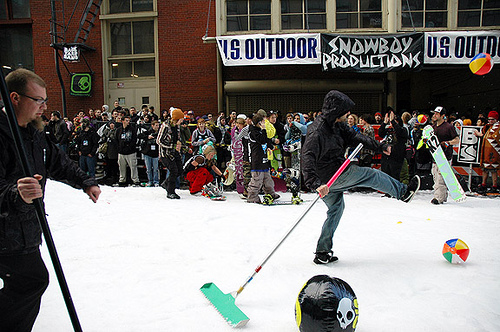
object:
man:
[184, 143, 227, 201]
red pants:
[185, 165, 215, 195]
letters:
[323, 35, 421, 69]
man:
[155, 100, 188, 197]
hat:
[174, 148, 187, 162]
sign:
[68, 70, 93, 94]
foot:
[400, 174, 421, 203]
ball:
[467, 51, 495, 76]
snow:
[31, 180, 497, 330]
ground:
[31, 177, 499, 328]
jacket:
[298, 121, 376, 192]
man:
[297, 83, 424, 264]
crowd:
[36, 97, 497, 193]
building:
[4, 3, 499, 129]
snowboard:
[420, 124, 466, 204]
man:
[423, 103, 463, 203]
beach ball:
[441, 238, 469, 267]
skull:
[335, 296, 355, 330]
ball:
[294, 275, 360, 330]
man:
[2, 68, 102, 330]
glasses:
[16, 92, 52, 106]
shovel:
[199, 141, 365, 330]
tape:
[327, 158, 350, 188]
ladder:
[43, 0, 104, 54]